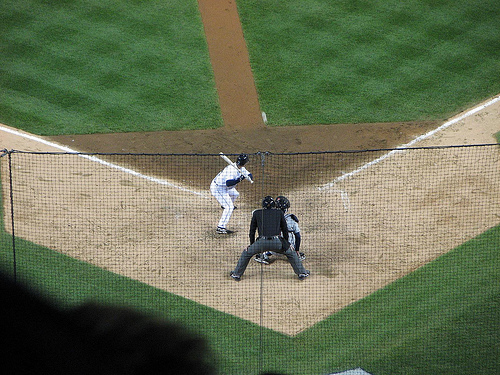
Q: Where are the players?
A: In the field.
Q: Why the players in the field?
A: To play.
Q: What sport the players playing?
A: Baseball.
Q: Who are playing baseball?
A: Players.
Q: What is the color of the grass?
A: Green.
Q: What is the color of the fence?
A: Black.